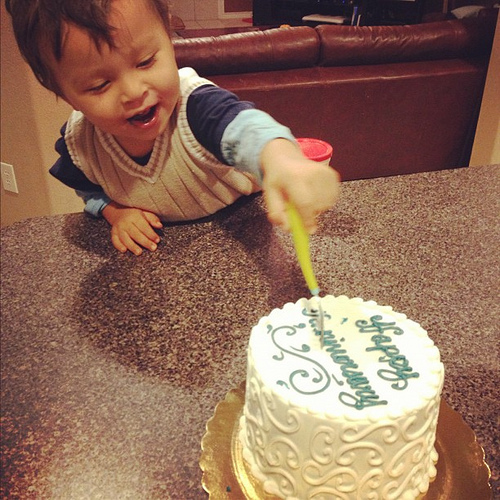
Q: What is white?
A: Frosting on cake.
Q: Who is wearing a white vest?
A: Boy.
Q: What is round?
A: A cake.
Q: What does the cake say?
A: "Happy Anniversary".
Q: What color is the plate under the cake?
A: Gold.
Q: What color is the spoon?
A: Yellow.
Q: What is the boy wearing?
A: A sweater vest.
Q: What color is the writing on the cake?
A: Blue.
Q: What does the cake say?
A: Happy Anniversary.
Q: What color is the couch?
A: Brown.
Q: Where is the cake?
A: On the counter top.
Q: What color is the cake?
A: White.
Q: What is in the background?
A: A couch.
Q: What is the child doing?
A: Touching the cake with a spoon.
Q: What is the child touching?
A: The cake.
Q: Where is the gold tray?
A: Under the cake.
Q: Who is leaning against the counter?
A: The boy.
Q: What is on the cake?
A: Writing.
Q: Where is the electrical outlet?
A: On the wall.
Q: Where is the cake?
A: On the counter.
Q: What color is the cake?
A: White.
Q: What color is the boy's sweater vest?
A: Tan.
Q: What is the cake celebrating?
A: An anniversary.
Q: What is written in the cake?
A: Happy Anniversary.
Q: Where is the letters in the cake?
A: Top of the cake.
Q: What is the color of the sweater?
A: Light brown.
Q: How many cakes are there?
A: 1.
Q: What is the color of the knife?
A: Yellow.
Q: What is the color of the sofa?
A: Brown.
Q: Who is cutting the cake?
A: The child.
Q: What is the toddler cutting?
A: A cake.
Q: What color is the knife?
A: Yellow.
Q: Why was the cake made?
A: For an anniversary.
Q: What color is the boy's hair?
A: Brown.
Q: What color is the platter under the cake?
A: Gold.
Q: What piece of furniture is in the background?
A: A couch.